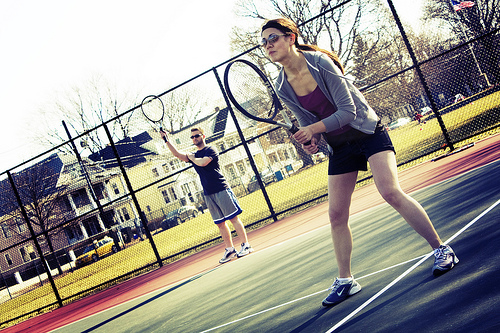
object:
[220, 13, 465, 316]
woman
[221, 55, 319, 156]
racket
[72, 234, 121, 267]
car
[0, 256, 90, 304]
street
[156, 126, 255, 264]
man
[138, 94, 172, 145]
racket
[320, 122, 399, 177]
shorts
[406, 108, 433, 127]
child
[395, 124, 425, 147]
grass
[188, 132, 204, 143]
sunglasses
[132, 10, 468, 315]
two persons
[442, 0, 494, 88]
post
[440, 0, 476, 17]
flag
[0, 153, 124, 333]
distance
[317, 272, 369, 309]
shoes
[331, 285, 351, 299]
logo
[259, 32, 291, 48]
sunglasses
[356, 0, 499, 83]
background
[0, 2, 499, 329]
fence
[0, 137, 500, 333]
tennis court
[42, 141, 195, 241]
row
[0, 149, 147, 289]
house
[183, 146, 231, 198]
tshirt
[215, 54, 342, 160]
tennis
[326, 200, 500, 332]
white lines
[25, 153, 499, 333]
ground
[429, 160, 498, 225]
shadow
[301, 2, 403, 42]
tree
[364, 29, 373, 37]
leaves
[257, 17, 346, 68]
hair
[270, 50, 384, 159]
sweatshirt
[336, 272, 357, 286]
white socks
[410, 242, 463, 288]
tennis shoes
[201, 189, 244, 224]
grey shorts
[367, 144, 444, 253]
leg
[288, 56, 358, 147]
arm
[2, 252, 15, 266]
windows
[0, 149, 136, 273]
building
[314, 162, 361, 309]
legs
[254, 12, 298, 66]
head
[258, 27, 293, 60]
face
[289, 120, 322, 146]
hands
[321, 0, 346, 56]
branches